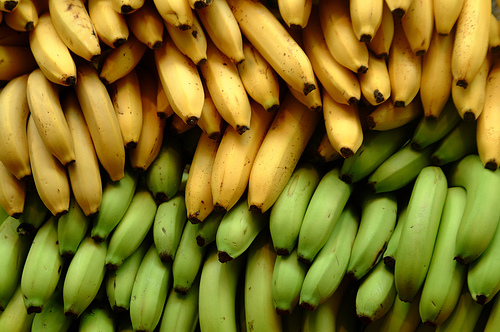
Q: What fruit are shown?
A: Bananas.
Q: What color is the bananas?
A: Yellow, green.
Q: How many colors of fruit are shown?
A: 2.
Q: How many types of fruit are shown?
A: 1.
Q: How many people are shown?
A: 0.